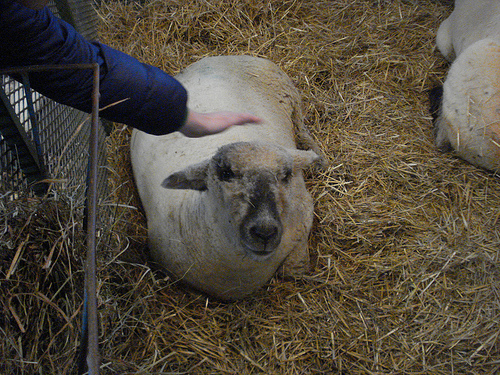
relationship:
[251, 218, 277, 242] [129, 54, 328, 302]
nose of sheep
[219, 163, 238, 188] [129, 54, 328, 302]
eye of sheep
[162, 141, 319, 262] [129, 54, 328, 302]
head of sheep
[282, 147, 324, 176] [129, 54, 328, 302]
ear of sheep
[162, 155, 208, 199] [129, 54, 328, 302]
ear of sheep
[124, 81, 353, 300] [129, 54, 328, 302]
wool on sheep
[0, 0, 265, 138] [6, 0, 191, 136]
person wearing coat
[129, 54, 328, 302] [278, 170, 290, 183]
sheep has eye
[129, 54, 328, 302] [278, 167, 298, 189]
sheep has eye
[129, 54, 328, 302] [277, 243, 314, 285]
sheep has leg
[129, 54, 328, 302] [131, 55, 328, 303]
sheep has fur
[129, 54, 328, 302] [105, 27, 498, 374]
sheep in hay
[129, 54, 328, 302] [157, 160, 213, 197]
sheep has ear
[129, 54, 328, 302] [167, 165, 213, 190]
sheep has ear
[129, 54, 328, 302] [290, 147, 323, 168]
sheep has ear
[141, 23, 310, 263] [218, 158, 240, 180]
sheep has eye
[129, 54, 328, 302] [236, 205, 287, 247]
sheep has nose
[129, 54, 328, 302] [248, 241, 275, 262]
sheep has mouth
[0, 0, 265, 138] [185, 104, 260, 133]
person has hand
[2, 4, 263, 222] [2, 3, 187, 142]
person has arm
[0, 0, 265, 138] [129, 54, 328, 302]
person pet sheep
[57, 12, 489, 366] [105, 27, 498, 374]
bedding made of hay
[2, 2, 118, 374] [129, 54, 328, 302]
fence contains sheep